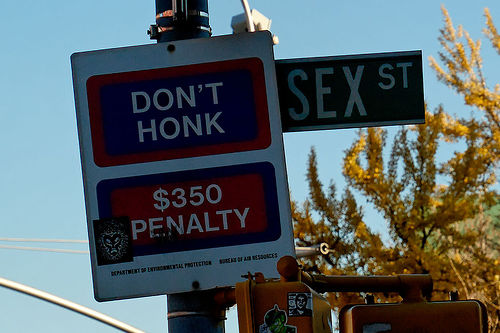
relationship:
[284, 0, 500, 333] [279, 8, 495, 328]
leaves on tree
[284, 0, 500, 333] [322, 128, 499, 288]
leaves on tree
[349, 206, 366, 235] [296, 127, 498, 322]
leaves on tree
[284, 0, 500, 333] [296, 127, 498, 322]
leaves on tree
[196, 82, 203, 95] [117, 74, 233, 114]
apostrophe in don't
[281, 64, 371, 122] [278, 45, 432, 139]
sex on a sign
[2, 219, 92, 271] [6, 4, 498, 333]
wires in sky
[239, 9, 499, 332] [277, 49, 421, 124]
tree behind sign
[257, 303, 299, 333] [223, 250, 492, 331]
sticker on traffic signal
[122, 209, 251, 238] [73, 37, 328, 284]
letters of sign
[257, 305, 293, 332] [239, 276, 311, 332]
sticker on traffic signal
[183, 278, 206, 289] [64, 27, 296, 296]
bolt holding sign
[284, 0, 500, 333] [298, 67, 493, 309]
leaves on tree